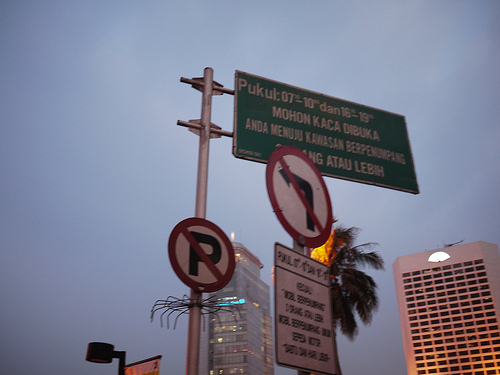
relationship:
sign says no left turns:
[267, 144, 331, 242] [277, 153, 323, 233]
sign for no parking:
[169, 219, 235, 293] [179, 230, 227, 279]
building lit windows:
[389, 239, 498, 373] [411, 257, 488, 371]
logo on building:
[425, 249, 451, 266] [389, 239, 498, 373]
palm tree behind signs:
[325, 221, 386, 337] [149, 74, 423, 370]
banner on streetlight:
[125, 353, 162, 374] [86, 339, 127, 374]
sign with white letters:
[232, 74, 422, 194] [235, 76, 407, 179]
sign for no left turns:
[267, 144, 331, 242] [277, 153, 323, 233]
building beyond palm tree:
[389, 239, 498, 373] [325, 221, 386, 337]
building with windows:
[389, 239, 498, 373] [411, 257, 488, 371]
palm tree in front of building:
[325, 221, 386, 337] [389, 239, 498, 373]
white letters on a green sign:
[235, 76, 407, 179] [232, 74, 422, 194]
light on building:
[219, 300, 252, 306] [197, 241, 271, 372]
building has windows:
[197, 241, 271, 372] [210, 291, 246, 375]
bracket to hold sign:
[179, 71, 233, 139] [232, 74, 422, 194]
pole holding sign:
[187, 58, 216, 375] [232, 74, 422, 194]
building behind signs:
[197, 241, 271, 372] [149, 74, 423, 370]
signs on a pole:
[149, 74, 423, 370] [187, 58, 216, 375]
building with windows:
[197, 241, 271, 372] [210, 291, 246, 375]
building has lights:
[197, 241, 271, 372] [211, 244, 275, 374]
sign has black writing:
[272, 241, 339, 374] [277, 248, 335, 362]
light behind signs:
[312, 214, 334, 267] [149, 74, 423, 370]